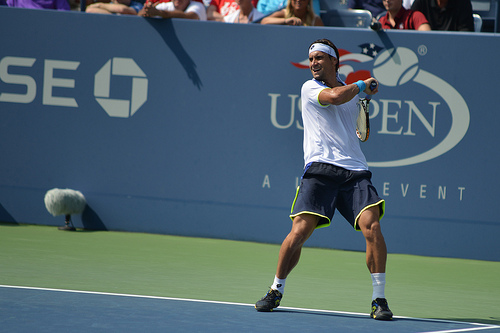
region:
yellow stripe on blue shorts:
[286, 183, 311, 218]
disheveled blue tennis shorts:
[285, 158, 402, 245]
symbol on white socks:
[270, 277, 292, 289]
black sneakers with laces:
[247, 283, 329, 327]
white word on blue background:
[243, 164, 282, 199]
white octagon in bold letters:
[91, 52, 186, 147]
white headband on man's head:
[302, 42, 365, 52]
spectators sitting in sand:
[141, 3, 381, 30]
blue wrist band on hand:
[351, 71, 375, 101]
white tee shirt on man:
[272, 81, 414, 168]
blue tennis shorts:
[286, 160, 401, 226]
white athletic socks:
[259, 268, 401, 300]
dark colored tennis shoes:
[246, 286, 399, 322]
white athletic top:
[294, 71, 389, 171]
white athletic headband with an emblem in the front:
[304, 42, 353, 62]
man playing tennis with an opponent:
[238, 35, 439, 325]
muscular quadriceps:
[285, 185, 416, 238]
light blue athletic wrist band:
[351, 76, 368, 96]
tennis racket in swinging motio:
[352, 82, 397, 147]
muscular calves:
[362, 239, 405, 279]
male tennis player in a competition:
[246, 41, 416, 331]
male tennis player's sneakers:
[203, 279, 405, 331]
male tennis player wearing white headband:
[298, 39, 341, 64]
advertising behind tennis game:
[3, 50, 498, 157]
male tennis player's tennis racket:
[349, 77, 390, 154]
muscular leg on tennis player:
[357, 204, 399, 289]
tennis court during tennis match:
[20, 240, 257, 327]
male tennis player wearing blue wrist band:
[347, 77, 374, 99]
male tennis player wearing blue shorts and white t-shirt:
[269, 80, 416, 232]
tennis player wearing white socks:
[261, 262, 399, 287]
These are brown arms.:
[134, 1, 213, 28]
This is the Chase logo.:
[0, 56, 177, 121]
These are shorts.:
[289, 123, 407, 248]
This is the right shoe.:
[241, 271, 296, 312]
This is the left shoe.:
[362, 285, 405, 328]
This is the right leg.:
[241, 180, 332, 311]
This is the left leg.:
[350, 187, 415, 328]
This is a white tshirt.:
[290, 68, 384, 180]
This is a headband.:
[305, 34, 338, 56]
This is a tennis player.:
[241, 24, 416, 321]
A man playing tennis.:
[230, 27, 425, 328]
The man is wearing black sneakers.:
[245, 275, 435, 320]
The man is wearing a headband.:
[285, 35, 336, 85]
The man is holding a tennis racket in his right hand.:
[280, 27, 380, 179]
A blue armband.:
[346, 72, 362, 92]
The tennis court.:
[20, 236, 175, 327]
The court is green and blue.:
[50, 245, 130, 320]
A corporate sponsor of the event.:
[5, 21, 170, 123]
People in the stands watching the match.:
[70, 0, 455, 45]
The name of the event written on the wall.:
[260, 46, 471, 221]